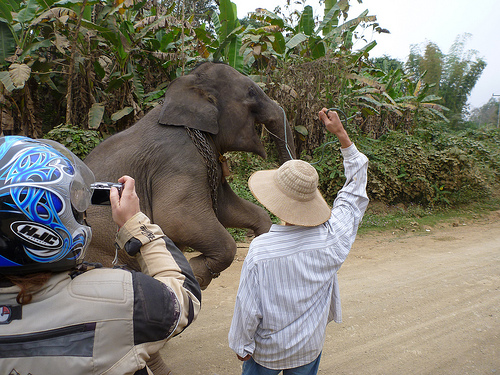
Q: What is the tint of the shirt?
A: Blue and white striped.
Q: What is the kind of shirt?
A: A long sleeve.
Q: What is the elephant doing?
A: A trick.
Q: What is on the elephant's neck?
A: Chain.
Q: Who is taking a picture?
A: Motorcycle man.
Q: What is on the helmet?
A: Blue flames.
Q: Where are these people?
A: Dirt road.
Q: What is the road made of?
A: Dirt.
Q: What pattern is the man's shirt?
A: Stripes.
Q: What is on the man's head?
A: Hat.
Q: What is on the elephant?
A: Rope.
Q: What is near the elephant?
A: Trees.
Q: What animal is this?
A: An elephant.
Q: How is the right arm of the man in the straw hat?
A: Raised in the air.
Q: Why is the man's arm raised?
A: He's getting the elephant to perform a trick.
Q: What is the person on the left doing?
A: Taking a photo.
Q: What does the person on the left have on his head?
A: A helmet.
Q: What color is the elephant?
A: Grey.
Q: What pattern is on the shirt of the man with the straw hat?
A: Stripes.